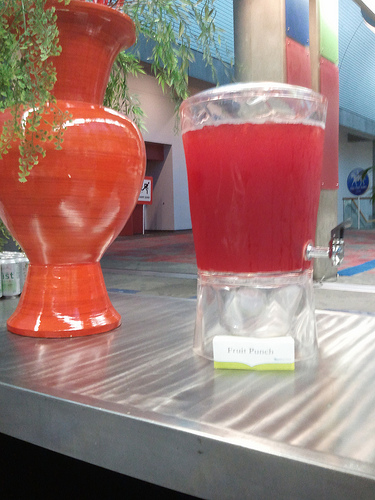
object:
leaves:
[1, 31, 8, 43]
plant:
[0, 0, 74, 186]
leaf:
[197, 30, 204, 42]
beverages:
[1, 256, 22, 301]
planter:
[0, 0, 237, 340]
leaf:
[56, 144, 63, 150]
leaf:
[168, 53, 176, 66]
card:
[213, 335, 294, 372]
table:
[0, 292, 375, 500]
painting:
[347, 167, 369, 196]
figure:
[141, 181, 151, 194]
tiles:
[283, 0, 309, 47]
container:
[178, 80, 345, 363]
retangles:
[314, 1, 338, 65]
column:
[286, 35, 311, 88]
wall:
[347, 138, 375, 230]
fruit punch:
[226, 346, 277, 358]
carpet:
[98, 230, 374, 300]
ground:
[97, 234, 374, 300]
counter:
[0, 288, 375, 500]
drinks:
[179, 121, 324, 277]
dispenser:
[180, 81, 344, 360]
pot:
[0, 0, 147, 340]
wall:
[339, 0, 375, 125]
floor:
[97, 232, 374, 301]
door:
[122, 204, 143, 234]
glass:
[192, 277, 319, 364]